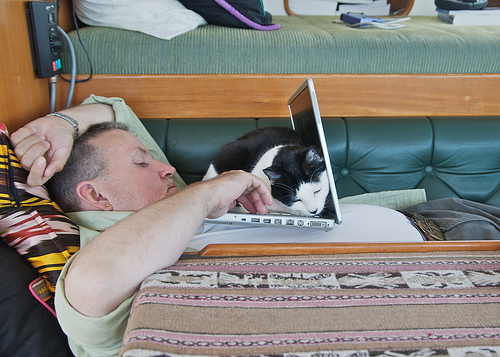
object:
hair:
[42, 119, 131, 214]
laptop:
[199, 76, 344, 230]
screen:
[274, 78, 342, 222]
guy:
[9, 92, 500, 357]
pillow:
[0, 120, 70, 290]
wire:
[37, 0, 94, 86]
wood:
[0, 1, 498, 257]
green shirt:
[53, 86, 427, 357]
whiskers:
[273, 182, 296, 199]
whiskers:
[309, 163, 329, 184]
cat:
[200, 125, 335, 220]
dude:
[5, 94, 286, 357]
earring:
[105, 203, 111, 208]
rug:
[118, 248, 499, 355]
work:
[6, 69, 369, 343]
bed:
[3, 0, 500, 122]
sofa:
[0, 108, 499, 357]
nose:
[306, 200, 318, 215]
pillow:
[71, 0, 213, 43]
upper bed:
[57, 14, 499, 121]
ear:
[261, 166, 283, 182]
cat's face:
[261, 147, 330, 216]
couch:
[3, 119, 496, 356]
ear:
[305, 145, 323, 163]